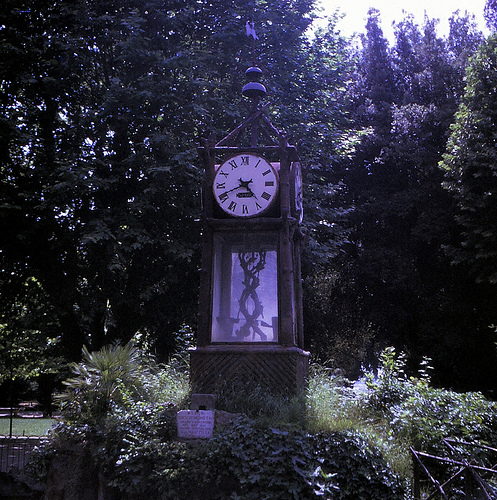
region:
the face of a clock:
[201, 143, 301, 223]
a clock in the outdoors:
[187, 66, 321, 429]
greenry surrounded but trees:
[23, 334, 170, 475]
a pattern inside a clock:
[207, 246, 287, 353]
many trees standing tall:
[15, 141, 179, 351]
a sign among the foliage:
[166, 401, 227, 449]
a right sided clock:
[287, 158, 316, 231]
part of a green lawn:
[11, 418, 49, 439]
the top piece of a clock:
[193, 23, 294, 149]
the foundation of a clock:
[180, 343, 326, 420]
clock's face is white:
[210, 152, 285, 229]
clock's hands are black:
[219, 174, 260, 203]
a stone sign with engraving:
[175, 408, 214, 437]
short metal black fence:
[0, 434, 40, 466]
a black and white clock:
[212, 150, 279, 219]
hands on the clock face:
[221, 177, 257, 201]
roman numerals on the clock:
[258, 166, 277, 200]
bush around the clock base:
[107, 406, 396, 493]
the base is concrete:
[184, 342, 310, 423]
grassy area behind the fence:
[2, 412, 53, 436]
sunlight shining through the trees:
[307, 5, 486, 42]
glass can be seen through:
[213, 232, 280, 339]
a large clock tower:
[185, 61, 316, 425]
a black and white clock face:
[214, 153, 275, 217]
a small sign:
[175, 406, 215, 440]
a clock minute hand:
[215, 178, 249, 197]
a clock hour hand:
[236, 174, 257, 198]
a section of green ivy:
[114, 428, 406, 499]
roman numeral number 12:
[238, 152, 251, 169]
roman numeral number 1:
[252, 154, 262, 168]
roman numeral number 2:
[259, 166, 270, 175]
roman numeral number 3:
[261, 176, 274, 188]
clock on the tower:
[200, 152, 307, 226]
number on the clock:
[235, 198, 250, 222]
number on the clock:
[237, 154, 249, 166]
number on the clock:
[261, 166, 280, 180]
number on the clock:
[216, 169, 226, 185]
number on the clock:
[209, 177, 226, 189]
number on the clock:
[221, 190, 228, 201]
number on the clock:
[257, 186, 273, 202]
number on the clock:
[221, 185, 233, 207]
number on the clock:
[256, 189, 266, 206]